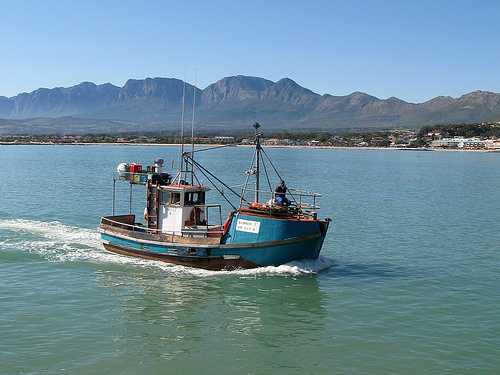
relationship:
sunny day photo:
[4, 7, 495, 107] [3, 4, 499, 368]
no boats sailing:
[329, 145, 499, 272] [94, 143, 331, 277]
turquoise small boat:
[93, 142, 345, 278] [66, 146, 367, 292]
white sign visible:
[227, 207, 271, 243] [228, 215, 275, 239]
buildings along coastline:
[1, 128, 499, 154] [1, 138, 499, 158]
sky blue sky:
[0, 0, 500, 105] [13, 5, 455, 105]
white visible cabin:
[141, 180, 220, 242] [150, 182, 215, 232]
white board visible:
[227, 207, 271, 243] [220, 201, 286, 251]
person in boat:
[248, 171, 308, 216] [94, 64, 334, 268]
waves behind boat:
[1, 191, 104, 271] [94, 64, 334, 268]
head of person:
[270, 173, 308, 185] [272, 178, 293, 214]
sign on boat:
[228, 215, 275, 239] [94, 64, 334, 268]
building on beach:
[428, 132, 484, 150] [278, 139, 498, 158]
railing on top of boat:
[246, 185, 324, 218] [66, 146, 367, 292]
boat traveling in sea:
[66, 146, 367, 292] [0, 145, 500, 370]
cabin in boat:
[150, 182, 215, 232] [154, 182, 206, 239]